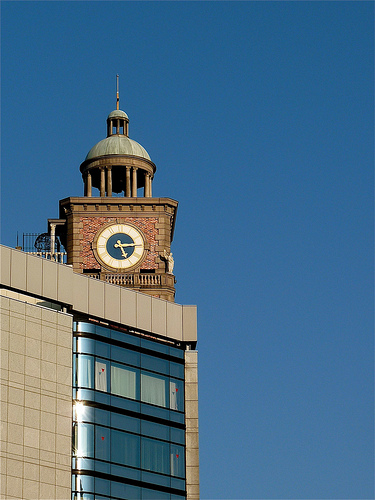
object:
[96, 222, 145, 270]
face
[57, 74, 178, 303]
tower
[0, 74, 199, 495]
building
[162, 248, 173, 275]
statue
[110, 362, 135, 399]
window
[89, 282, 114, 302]
fence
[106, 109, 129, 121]
dome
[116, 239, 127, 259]
hand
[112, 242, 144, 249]
hand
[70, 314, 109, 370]
trim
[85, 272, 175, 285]
railing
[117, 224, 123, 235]
numeral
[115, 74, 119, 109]
pole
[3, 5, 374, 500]
sky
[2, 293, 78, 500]
wall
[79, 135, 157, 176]
dome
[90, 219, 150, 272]
bell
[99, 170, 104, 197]
pillar